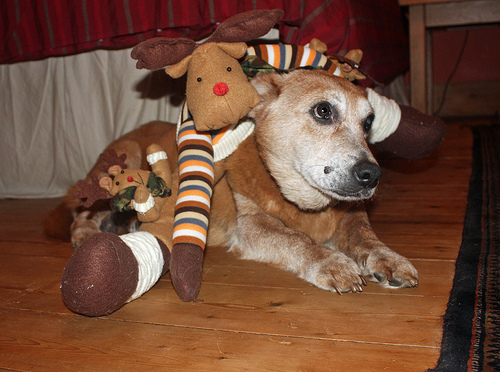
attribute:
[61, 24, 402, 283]
toys — piled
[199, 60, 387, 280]
dog — small, brown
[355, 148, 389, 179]
nose — red , black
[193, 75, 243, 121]
nose — red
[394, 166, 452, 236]
floor — hard, wooden, color, orang, brown, wood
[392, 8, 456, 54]
table — wooden, wood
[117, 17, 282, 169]
reindeer — christmas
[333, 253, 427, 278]
paw — white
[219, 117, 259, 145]
skirt — white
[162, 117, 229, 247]
sweater — multi color, striped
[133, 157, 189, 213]
mistletoe — green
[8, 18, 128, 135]
bed — colored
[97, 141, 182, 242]
moose — stuffed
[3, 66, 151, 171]
cloth — white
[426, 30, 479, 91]
cord — black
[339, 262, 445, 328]
nail — brown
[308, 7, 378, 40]
material — red